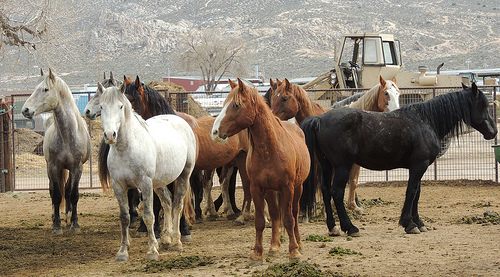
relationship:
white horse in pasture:
[22, 71, 89, 236] [318, 244, 496, 274]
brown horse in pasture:
[197, 77, 314, 216] [318, 244, 496, 274]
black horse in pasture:
[318, 96, 497, 165] [318, 244, 496, 274]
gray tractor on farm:
[302, 48, 485, 105] [24, 60, 500, 165]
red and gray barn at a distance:
[158, 67, 234, 104] [141, 39, 264, 117]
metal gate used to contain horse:
[98, 84, 497, 191] [22, 71, 89, 236]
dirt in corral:
[364, 203, 388, 242] [5, 85, 500, 231]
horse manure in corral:
[22, 71, 89, 236] [5, 85, 500, 231]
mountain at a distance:
[38, 8, 498, 36] [141, 39, 264, 117]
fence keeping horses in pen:
[24, 60, 500, 165] [5, 85, 500, 231]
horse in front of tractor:
[22, 71, 89, 236] [286, 12, 478, 118]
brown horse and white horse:
[197, 77, 314, 216] [97, 82, 197, 259]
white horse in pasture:
[80, 96, 230, 230] [318, 244, 496, 274]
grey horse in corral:
[6, 80, 9, 81] [5, 85, 500, 231]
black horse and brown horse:
[318, 96, 497, 165] [197, 77, 314, 216]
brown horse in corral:
[197, 77, 314, 216] [5, 85, 500, 231]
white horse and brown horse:
[80, 96, 230, 230] [197, 77, 314, 216]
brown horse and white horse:
[197, 77, 314, 216] [80, 96, 230, 230]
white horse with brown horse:
[80, 96, 230, 230] [197, 77, 314, 216]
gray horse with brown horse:
[22, 71, 89, 236] [197, 77, 314, 216]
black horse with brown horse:
[318, 96, 497, 165] [197, 77, 314, 216]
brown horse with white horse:
[197, 77, 314, 216] [80, 96, 230, 230]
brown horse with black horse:
[197, 77, 314, 216] [318, 96, 497, 165]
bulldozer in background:
[286, 12, 478, 118] [46, 16, 489, 98]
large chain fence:
[37, 81, 498, 106] [87, 67, 497, 114]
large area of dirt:
[13, 105, 498, 174] [364, 203, 388, 242]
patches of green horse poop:
[308, 223, 358, 269] [289, 195, 391, 273]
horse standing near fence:
[22, 71, 89, 236] [87, 67, 497, 114]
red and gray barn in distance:
[158, 67, 234, 104] [141, 39, 264, 117]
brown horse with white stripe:
[197, 77, 314, 216] [196, 80, 232, 144]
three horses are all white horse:
[21, 66, 166, 177] [80, 96, 230, 230]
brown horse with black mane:
[197, 77, 314, 216] [136, 82, 171, 119]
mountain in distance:
[38, 8, 498, 36] [141, 39, 264, 117]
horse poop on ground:
[467, 185, 492, 240] [434, 181, 471, 236]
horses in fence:
[5, 85, 500, 231] [3, 84, 496, 191]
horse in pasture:
[97, 82, 197, 259] [318, 244, 496, 274]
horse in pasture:
[22, 71, 89, 236] [318, 244, 496, 274]